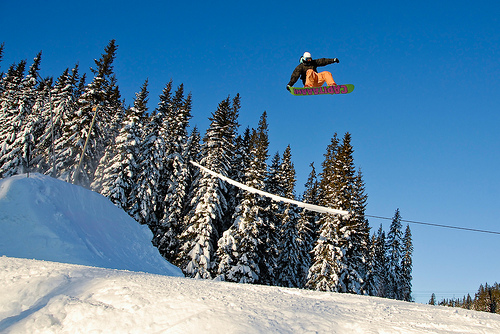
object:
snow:
[0, 168, 498, 334]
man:
[282, 43, 359, 94]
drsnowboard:
[288, 82, 355, 97]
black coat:
[288, 56, 334, 86]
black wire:
[364, 214, 500, 235]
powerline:
[186, 158, 500, 236]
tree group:
[426, 280, 499, 312]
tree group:
[1, 38, 414, 300]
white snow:
[1, 174, 500, 334]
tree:
[0, 35, 419, 305]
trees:
[4, 38, 414, 305]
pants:
[303, 69, 336, 88]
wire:
[157, 134, 499, 234]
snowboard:
[287, 83, 354, 96]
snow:
[0, 173, 185, 277]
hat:
[302, 52, 311, 61]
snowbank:
[1, 171, 186, 280]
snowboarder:
[286, 52, 364, 105]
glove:
[334, 58, 339, 64]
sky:
[0, 1, 499, 308]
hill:
[0, 171, 187, 276]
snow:
[0, 253, 498, 334]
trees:
[428, 279, 496, 310]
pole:
[72, 107, 99, 183]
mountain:
[1, 172, 500, 334]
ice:
[190, 159, 348, 216]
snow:
[199, 147, 219, 273]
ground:
[0, 173, 500, 334]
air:
[29, 12, 485, 185]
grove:
[0, 37, 412, 303]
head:
[296, 50, 316, 68]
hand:
[333, 57, 339, 64]